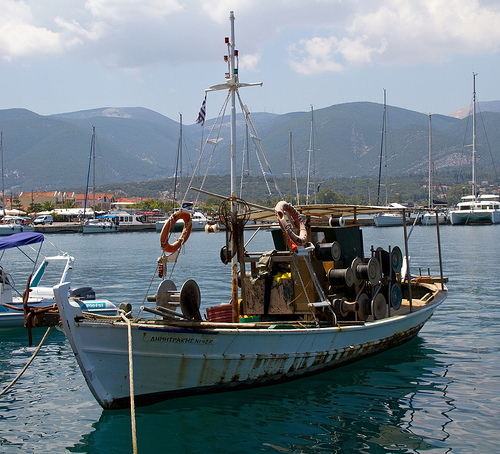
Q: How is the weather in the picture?
A: It is cloudy.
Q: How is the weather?
A: It is cloudy.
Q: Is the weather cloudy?
A: Yes, it is cloudy.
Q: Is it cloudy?
A: Yes, it is cloudy.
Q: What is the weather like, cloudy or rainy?
A: It is cloudy.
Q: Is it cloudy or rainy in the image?
A: It is cloudy.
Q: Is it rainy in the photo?
A: No, it is cloudy.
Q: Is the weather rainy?
A: No, it is cloudy.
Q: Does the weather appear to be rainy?
A: No, it is cloudy.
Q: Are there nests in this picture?
A: No, there are no nests.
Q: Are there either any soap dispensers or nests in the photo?
A: No, there are no nests or soap dispensers.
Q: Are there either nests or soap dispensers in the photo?
A: No, there are no nests or soap dispensers.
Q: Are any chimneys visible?
A: No, there are no chimneys.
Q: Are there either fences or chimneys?
A: No, there are no chimneys or fences.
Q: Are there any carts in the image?
A: No, there are no carts.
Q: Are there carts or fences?
A: No, there are no carts or fences.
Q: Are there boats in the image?
A: Yes, there is a boat.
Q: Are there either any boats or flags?
A: Yes, there is a boat.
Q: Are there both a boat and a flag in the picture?
A: Yes, there are both a boat and a flag.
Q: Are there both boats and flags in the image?
A: Yes, there are both a boat and a flag.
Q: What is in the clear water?
A: The boat is in the water.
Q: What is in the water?
A: The boat is in the water.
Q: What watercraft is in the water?
A: The watercraft is a boat.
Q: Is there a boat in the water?
A: Yes, there is a boat in the water.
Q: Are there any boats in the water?
A: Yes, there is a boat in the water.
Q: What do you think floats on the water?
A: The boats float on the water.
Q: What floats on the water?
A: The boats float on the water.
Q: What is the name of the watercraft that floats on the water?
A: The watercraft is boats.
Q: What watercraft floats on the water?
A: The watercraft is boats.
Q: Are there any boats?
A: Yes, there is a boat.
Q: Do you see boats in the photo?
A: Yes, there is a boat.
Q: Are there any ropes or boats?
A: Yes, there is a boat.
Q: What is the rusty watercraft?
A: The watercraft is a boat.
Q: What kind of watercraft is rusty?
A: The watercraft is a boat.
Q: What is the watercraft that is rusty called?
A: The watercraft is a boat.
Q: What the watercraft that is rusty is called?
A: The watercraft is a boat.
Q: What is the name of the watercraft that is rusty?
A: The watercraft is a boat.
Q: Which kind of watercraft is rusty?
A: The watercraft is a boat.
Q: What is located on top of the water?
A: The boat is on top of the water.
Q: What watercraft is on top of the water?
A: The watercraft is a boat.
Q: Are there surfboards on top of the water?
A: No, there is a boat on top of the water.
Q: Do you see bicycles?
A: No, there are no bicycles.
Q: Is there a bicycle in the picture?
A: No, there are no bicycles.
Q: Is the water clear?
A: Yes, the water is clear.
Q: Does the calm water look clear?
A: Yes, the water is clear.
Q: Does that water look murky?
A: No, the water is clear.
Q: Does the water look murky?
A: No, the water is clear.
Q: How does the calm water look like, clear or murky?
A: The water is clear.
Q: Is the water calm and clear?
A: Yes, the water is calm and clear.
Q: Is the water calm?
A: Yes, the water is calm.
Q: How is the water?
A: The water is calm.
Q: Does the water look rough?
A: No, the water is calm.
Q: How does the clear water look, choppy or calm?
A: The water is calm.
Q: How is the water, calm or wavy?
A: The water is calm.